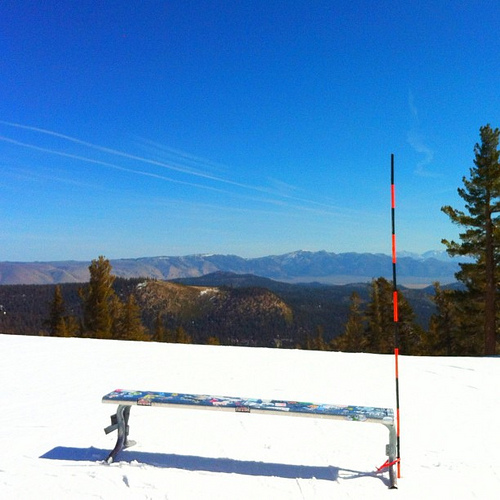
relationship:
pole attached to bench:
[389, 152, 401, 478] [100, 387, 398, 489]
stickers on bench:
[100, 385, 399, 426] [100, 387, 398, 489]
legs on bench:
[94, 391, 158, 455] [93, 370, 404, 490]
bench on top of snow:
[100, 387, 398, 489] [2, 335, 495, 497]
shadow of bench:
[155, 452, 346, 492] [98, 377, 426, 498]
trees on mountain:
[262, 267, 408, 307] [0, 250, 478, 355]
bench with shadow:
[100, 387, 398, 489] [38, 445, 390, 490]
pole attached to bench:
[389, 152, 413, 481] [94, 373, 399, 498]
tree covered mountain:
[37, 255, 307, 346] [6, 269, 322, 344]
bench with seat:
[94, 373, 399, 498] [109, 381, 399, 433]